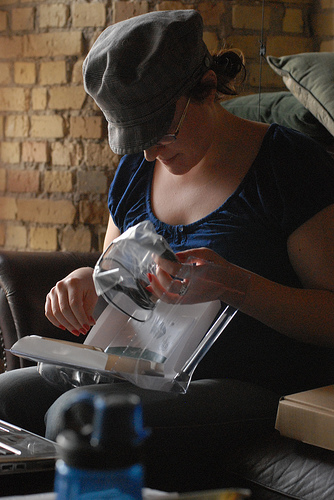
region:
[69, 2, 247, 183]
head of a person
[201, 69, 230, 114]
ear of a person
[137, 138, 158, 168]
nose of a person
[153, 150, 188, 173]
mouth of a person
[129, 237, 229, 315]
hand of a person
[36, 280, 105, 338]
hand of a person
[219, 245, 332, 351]
arm of a person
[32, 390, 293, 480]
leg of a person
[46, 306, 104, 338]
fingers of a person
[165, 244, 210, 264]
thumb of a person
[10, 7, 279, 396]
a woman unpacking an electronic device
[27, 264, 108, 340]
fingers with red fingernail polish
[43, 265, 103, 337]
the hand of a woman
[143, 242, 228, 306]
the hand of a woman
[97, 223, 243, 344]
a hand holding plastic around an electronic device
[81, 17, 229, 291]
a woman looking down at her hand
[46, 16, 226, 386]
a woman opening a plastic box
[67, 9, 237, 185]
a woman wearing a blue cap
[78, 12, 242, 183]
a woman wearing glasses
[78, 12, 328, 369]
a woman wearing a blue blouse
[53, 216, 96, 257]
brick in building wall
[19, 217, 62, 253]
brick in building wall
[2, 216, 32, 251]
brick in building wall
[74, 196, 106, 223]
brick in building wall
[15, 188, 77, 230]
brick in building wall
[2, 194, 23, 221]
brick in building wall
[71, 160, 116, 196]
brick in building wall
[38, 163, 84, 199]
brick in building wall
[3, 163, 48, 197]
brick in building wall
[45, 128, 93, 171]
brick in building wall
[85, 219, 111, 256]
brown brick in building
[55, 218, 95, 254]
brown brick in building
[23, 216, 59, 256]
brown brick in building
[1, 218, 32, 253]
brown brick in building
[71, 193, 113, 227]
brown brick in building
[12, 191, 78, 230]
brown brick in building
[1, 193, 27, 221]
brown brick in building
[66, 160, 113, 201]
brown brick in building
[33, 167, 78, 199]
brown brick in building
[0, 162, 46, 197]
brown brick in building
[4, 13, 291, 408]
a woman opens a package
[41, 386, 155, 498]
a water bottle sits on the table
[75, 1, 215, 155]
the woman wears a hat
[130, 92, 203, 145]
the woman wears glasses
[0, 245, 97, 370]
the sofas arm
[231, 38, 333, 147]
two throw pillows are behind the woman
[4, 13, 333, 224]
the wall behind the woman appears to be made of bricks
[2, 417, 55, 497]
an item is to the left of the water bottle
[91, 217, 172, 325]
the item is in a plastic sack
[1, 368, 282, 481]
the woman is wearing pants